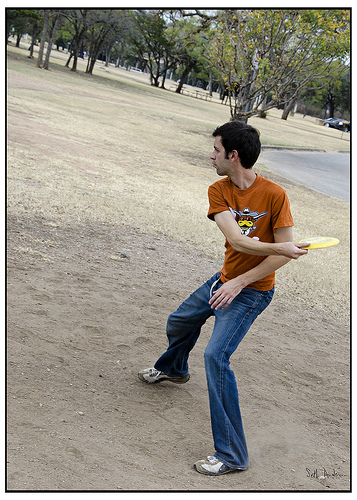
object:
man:
[138, 120, 310, 475]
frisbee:
[294, 236, 340, 251]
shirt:
[207, 175, 294, 293]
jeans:
[154, 272, 275, 470]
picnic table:
[191, 89, 212, 101]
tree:
[204, 10, 348, 124]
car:
[323, 116, 351, 132]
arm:
[211, 201, 276, 257]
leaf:
[303, 10, 310, 19]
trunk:
[35, 9, 49, 67]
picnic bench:
[168, 83, 189, 97]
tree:
[162, 17, 221, 94]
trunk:
[71, 38, 78, 71]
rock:
[78, 410, 84, 416]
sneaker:
[193, 455, 236, 477]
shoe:
[137, 366, 190, 385]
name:
[306, 467, 347, 479]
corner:
[300, 453, 351, 493]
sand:
[7, 221, 352, 491]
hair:
[212, 120, 261, 171]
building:
[111, 47, 173, 82]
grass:
[8, 41, 349, 317]